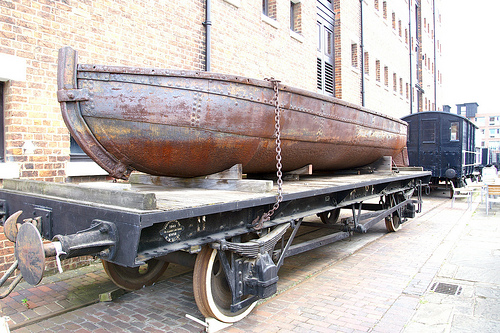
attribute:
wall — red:
[90, 6, 185, 58]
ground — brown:
[0, 200, 497, 328]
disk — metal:
[11, 218, 50, 296]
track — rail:
[22, 125, 483, 331]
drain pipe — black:
[357, 1, 368, 109]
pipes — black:
[183, 16, 225, 77]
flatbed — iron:
[0, 165, 442, 331]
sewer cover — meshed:
[424, 280, 458, 295]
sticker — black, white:
[160, 220, 183, 245]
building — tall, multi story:
[440, 98, 495, 187]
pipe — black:
[202, 2, 213, 72]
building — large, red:
[81, 14, 408, 98]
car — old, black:
[411, 82, 499, 207]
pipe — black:
[203, 0, 213, 72]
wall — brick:
[0, 0, 442, 287]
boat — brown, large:
[52, 42, 409, 179]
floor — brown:
[308, 262, 389, 322]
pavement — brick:
[1, 177, 498, 331]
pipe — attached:
[197, 2, 217, 72]